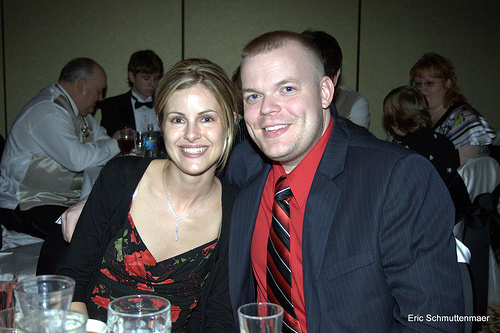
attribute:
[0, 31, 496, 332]
people — background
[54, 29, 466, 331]
man — smiling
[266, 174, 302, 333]
tie — striped, red, black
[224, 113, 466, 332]
jacket — striped, gray, black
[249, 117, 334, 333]
shirt — red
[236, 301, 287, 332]
flute — top, clear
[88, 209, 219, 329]
dress — flowered, floral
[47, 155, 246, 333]
sweater — black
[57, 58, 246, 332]
woman — smiling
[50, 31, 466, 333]
couple — smiling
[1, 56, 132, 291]
man — balding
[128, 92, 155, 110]
bowtie — black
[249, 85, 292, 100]
eyes — blue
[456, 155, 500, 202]
cover — silk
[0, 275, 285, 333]
glasses — various sizes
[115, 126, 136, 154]
glass — sitting